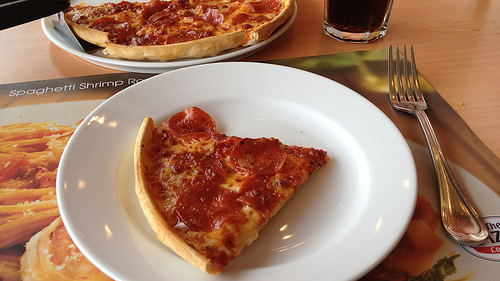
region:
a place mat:
[23, 93, 61, 131]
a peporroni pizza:
[138, 128, 293, 245]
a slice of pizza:
[139, 127, 304, 226]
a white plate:
[331, 177, 385, 226]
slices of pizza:
[103, 6, 250, 37]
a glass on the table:
[321, 10, 396, 46]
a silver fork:
[381, 53, 483, 223]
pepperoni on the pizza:
[182, 183, 229, 220]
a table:
[441, 12, 495, 94]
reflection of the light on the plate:
[370, 203, 392, 258]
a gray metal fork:
[381, 37, 490, 251]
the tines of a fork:
[386, 39, 428, 116]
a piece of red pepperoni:
[165, 102, 226, 137]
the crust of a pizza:
[129, 108, 229, 275]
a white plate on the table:
[53, 55, 426, 279]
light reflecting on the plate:
[85, 105, 125, 133]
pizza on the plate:
[116, 98, 341, 273]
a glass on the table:
[320, 1, 396, 52]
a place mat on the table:
[0, 44, 499, 279]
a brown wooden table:
[0, 1, 499, 164]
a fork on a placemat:
[380, 37, 487, 250]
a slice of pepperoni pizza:
[126, 105, 326, 275]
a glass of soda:
[320, 0, 391, 45]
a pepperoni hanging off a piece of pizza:
[170, 101, 210, 121]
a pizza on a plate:
[38, 1, 303, 61]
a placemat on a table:
[2, 44, 497, 279]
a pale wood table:
[1, 0, 498, 181]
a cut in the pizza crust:
[235, 25, 261, 46]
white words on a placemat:
[7, 73, 148, 102]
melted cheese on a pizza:
[217, 214, 255, 251]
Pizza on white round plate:
[135, 101, 331, 273]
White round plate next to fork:
[55, 56, 415, 277]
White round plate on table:
[56, 61, 412, 277]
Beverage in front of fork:
[322, 0, 389, 40]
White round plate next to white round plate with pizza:
[55, 62, 422, 279]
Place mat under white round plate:
[0, 45, 498, 278]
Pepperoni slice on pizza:
[163, 101, 213, 137]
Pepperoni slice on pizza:
[228, 131, 288, 172]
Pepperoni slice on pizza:
[175, 180, 243, 225]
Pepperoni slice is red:
[177, 183, 232, 229]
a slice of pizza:
[133, 99, 337, 279]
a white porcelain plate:
[52, 58, 423, 279]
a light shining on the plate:
[84, 104, 124, 137]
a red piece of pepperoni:
[163, 100, 218, 135]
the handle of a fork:
[414, 107, 492, 249]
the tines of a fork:
[383, 35, 430, 103]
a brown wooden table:
[0, 0, 499, 279]